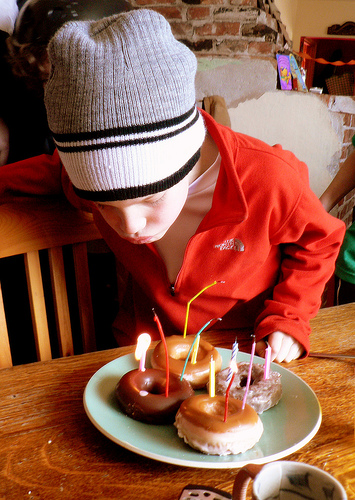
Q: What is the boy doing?
A: Blowing out candles.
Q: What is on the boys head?
A: A beanie.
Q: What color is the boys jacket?
A: Red.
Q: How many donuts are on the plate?
A: Four.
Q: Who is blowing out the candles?
A: A boy.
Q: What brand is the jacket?
A: North Face.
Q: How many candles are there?
A: Eleven.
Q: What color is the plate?
A: Blue.